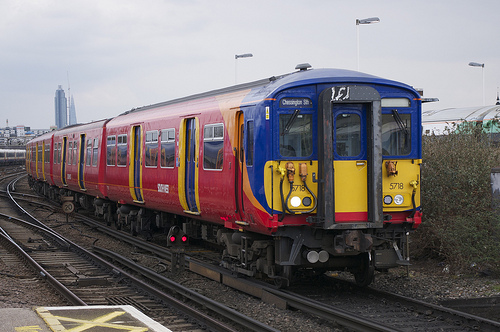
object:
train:
[22, 61, 426, 293]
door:
[182, 114, 201, 215]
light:
[301, 196, 312, 207]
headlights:
[393, 194, 404, 206]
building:
[53, 83, 67, 130]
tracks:
[12, 198, 51, 227]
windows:
[158, 127, 178, 169]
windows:
[332, 109, 365, 160]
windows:
[381, 112, 415, 158]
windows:
[144, 128, 159, 169]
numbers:
[393, 183, 397, 190]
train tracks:
[0, 230, 91, 307]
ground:
[0, 164, 500, 331]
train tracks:
[76, 215, 395, 332]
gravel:
[327, 257, 500, 307]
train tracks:
[374, 287, 500, 326]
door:
[130, 122, 144, 203]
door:
[79, 133, 86, 191]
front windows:
[275, 111, 318, 160]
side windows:
[199, 120, 224, 172]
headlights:
[383, 194, 394, 204]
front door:
[235, 110, 246, 224]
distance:
[53, 68, 78, 129]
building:
[68, 93, 76, 126]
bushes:
[430, 193, 443, 212]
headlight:
[289, 196, 301, 208]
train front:
[258, 67, 424, 270]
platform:
[0, 303, 174, 332]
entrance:
[331, 102, 370, 225]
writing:
[281, 98, 309, 107]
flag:
[468, 62, 484, 68]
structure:
[421, 104, 500, 135]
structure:
[489, 171, 499, 196]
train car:
[52, 117, 113, 200]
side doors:
[61, 134, 69, 186]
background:
[0, 0, 499, 129]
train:
[0, 148, 27, 167]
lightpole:
[66, 69, 71, 125]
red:
[203, 173, 231, 212]